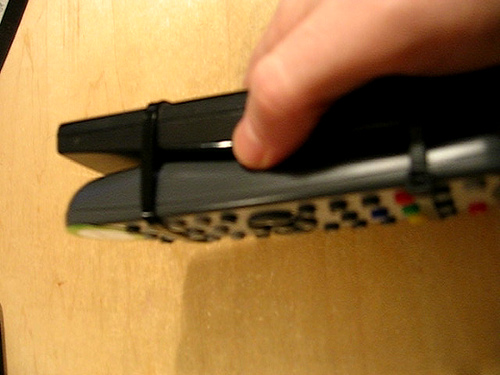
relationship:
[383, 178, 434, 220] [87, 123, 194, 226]
button on remotes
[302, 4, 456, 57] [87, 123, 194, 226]
hand holding remotes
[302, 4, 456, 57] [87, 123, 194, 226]
hand on remotes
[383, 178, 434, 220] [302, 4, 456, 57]
button on hand